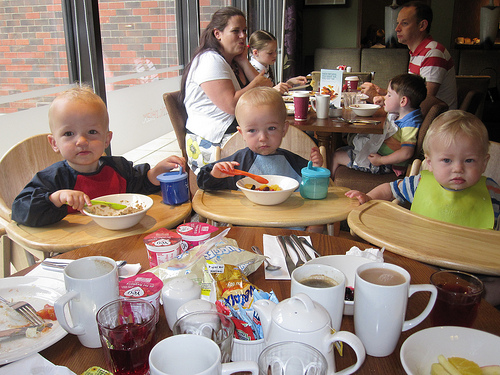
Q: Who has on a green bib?
A: The baby to the right.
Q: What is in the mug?
A: Coffee.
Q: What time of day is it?
A: Breakfast.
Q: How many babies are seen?
A: Three.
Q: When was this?
A: Day.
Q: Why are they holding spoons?
A: To eat.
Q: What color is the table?
A: Brown.